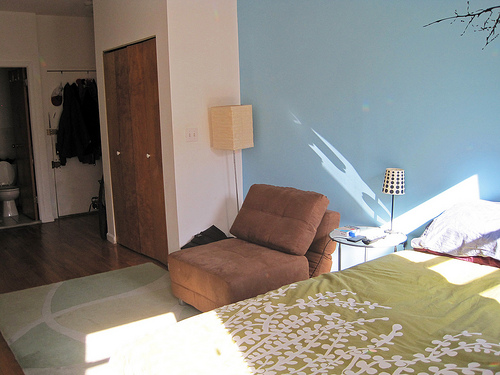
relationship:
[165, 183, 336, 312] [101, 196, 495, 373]
chair in bed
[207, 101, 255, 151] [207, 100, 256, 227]
shade on lamp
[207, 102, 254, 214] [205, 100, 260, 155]
lamp has shade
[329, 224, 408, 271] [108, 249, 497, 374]
table beside bed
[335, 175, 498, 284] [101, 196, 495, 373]
sunlight on bed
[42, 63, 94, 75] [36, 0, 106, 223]
bar in closet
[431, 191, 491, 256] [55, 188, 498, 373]
pillow on bed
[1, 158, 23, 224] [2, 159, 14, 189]
toilet has lid